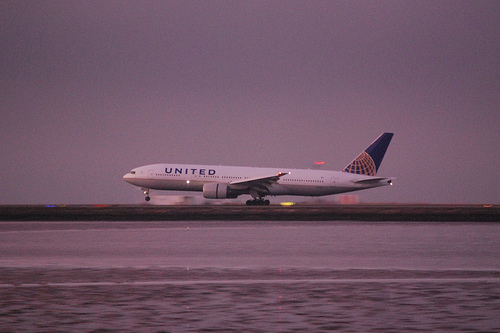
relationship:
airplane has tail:
[123, 132, 394, 205] [343, 131, 394, 173]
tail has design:
[343, 131, 394, 173] [344, 150, 377, 174]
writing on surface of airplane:
[165, 165, 217, 176] [123, 132, 394, 205]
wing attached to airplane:
[229, 171, 291, 190] [123, 132, 394, 205]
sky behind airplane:
[0, 0, 500, 205] [123, 132, 394, 205]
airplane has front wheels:
[123, 132, 394, 205] [144, 194, 151, 201]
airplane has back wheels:
[123, 132, 394, 205] [245, 200, 270, 207]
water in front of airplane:
[0, 220, 500, 332] [123, 132, 394, 205]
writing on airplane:
[165, 165, 217, 176] [123, 132, 394, 205]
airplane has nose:
[123, 132, 394, 205] [123, 167, 140, 184]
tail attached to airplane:
[343, 131, 394, 173] [123, 132, 394, 205]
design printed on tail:
[344, 150, 377, 174] [343, 131, 394, 173]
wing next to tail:
[354, 176, 386, 184] [343, 131, 394, 173]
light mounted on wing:
[278, 171, 282, 176] [229, 171, 291, 190]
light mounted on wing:
[288, 172, 291, 176] [229, 171, 291, 190]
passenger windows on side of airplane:
[149, 172, 251, 180] [123, 132, 394, 205]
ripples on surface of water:
[0, 264, 499, 329] [0, 220, 500, 332]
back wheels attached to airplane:
[245, 200, 270, 207] [123, 132, 394, 205]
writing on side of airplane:
[165, 165, 217, 176] [123, 132, 394, 205]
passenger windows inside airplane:
[281, 177, 326, 184] [123, 132, 394, 205]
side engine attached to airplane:
[201, 181, 236, 200] [123, 132, 394, 205]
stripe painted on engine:
[214, 182, 220, 199] [201, 181, 236, 200]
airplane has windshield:
[123, 132, 394, 205] [128, 169, 136, 174]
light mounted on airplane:
[389, 182, 394, 187] [123, 132, 394, 205]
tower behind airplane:
[312, 159, 329, 205] [123, 132, 394, 205]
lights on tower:
[313, 161, 323, 166] [312, 159, 329, 205]